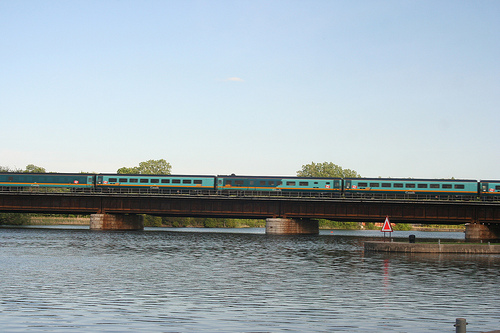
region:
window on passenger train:
[455, 183, 468, 190]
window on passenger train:
[438, 183, 451, 190]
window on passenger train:
[427, 178, 439, 188]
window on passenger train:
[413, 180, 425, 193]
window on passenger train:
[406, 179, 416, 188]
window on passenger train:
[394, 178, 406, 194]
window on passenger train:
[368, 179, 380, 190]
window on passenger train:
[357, 178, 366, 190]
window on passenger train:
[297, 178, 306, 190]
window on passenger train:
[283, 175, 296, 189]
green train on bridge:
[68, 165, 493, 237]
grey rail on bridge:
[19, 171, 490, 210]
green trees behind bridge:
[100, 157, 372, 223]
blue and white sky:
[135, 33, 319, 168]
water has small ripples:
[131, 239, 290, 321]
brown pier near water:
[365, 234, 491, 256]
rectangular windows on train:
[124, 171, 438, 194]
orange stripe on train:
[84, 183, 481, 190]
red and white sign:
[379, 212, 409, 251]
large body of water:
[1, 225, 348, 332]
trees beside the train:
[127, 161, 179, 178]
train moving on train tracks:
[100, 174, 499, 206]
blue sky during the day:
[3, 2, 485, 117]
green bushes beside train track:
[147, 219, 254, 230]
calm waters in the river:
[8, 227, 265, 313]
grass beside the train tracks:
[404, 237, 474, 252]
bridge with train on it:
[3, 196, 492, 220]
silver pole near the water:
[443, 314, 466, 331]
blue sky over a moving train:
[2, 0, 497, 157]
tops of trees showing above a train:
[2, 150, 359, 176]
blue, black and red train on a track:
[1, 174, 497, 195]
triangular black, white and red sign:
[380, 215, 394, 243]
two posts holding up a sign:
[382, 230, 393, 242]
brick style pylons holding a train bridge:
[83, 211, 492, 243]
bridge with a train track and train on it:
[0, 192, 492, 239]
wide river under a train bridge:
[2, 219, 496, 327]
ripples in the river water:
[103, 242, 362, 315]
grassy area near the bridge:
[27, 212, 86, 225]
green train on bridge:
[24, 163, 482, 208]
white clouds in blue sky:
[38, 28, 86, 72]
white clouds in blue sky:
[217, 32, 281, 79]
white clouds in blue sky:
[80, 1, 151, 46]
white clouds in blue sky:
[51, 25, 96, 57]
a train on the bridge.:
[106, 169, 479, 203]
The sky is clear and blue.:
[78, 31, 483, 136]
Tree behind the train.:
[296, 151, 365, 190]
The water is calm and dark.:
[76, 234, 356, 317]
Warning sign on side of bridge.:
[373, 208, 398, 238]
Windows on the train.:
[96, 171, 198, 184]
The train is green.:
[351, 167, 496, 198]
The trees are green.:
[116, 145, 347, 189]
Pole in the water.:
[448, 309, 472, 330]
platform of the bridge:
[91, 215, 153, 232]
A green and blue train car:
[208, 143, 343, 211]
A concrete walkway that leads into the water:
[357, 225, 463, 287]